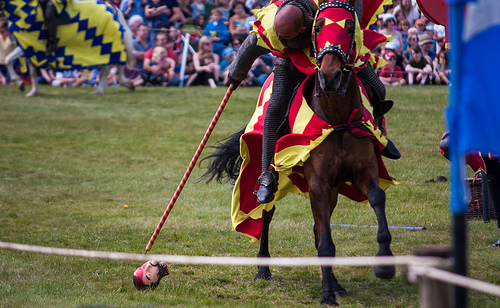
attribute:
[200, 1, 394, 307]
horse — yellow, red, brown, photographed, dark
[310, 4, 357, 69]
mask — red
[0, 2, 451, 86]
people — crowd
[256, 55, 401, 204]
legging — black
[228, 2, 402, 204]
man — gray, shaved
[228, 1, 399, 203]
armor — red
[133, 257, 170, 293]
head — fake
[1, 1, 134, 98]
horse — white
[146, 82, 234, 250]
spear — red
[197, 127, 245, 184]
tail — black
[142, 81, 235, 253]
pole — striped